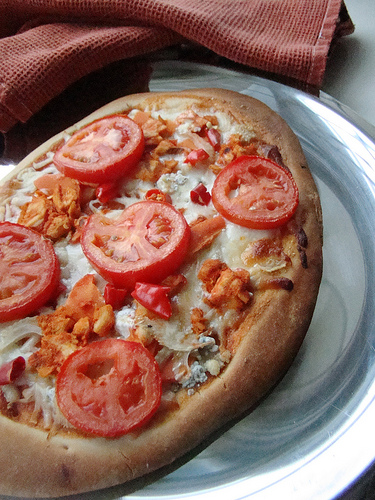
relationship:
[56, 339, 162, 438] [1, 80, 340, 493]
tomato atop pizza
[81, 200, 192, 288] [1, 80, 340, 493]
tomato atop pizza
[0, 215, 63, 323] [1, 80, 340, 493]
tomato atop pizza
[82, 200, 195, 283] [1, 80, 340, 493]
tomato atop pizza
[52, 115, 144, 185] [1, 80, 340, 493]
tomato atop pizza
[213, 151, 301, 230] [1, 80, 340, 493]
tomato atop pizza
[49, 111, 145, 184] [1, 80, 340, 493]
tomato atop pizza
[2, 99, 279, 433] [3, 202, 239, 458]
cheese atop pizza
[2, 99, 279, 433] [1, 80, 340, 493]
cheese on top pizza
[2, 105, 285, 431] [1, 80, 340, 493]
cheese melted on top pizza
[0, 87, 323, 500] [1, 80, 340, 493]
crust on pizza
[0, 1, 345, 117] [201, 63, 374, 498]
handcloth for plate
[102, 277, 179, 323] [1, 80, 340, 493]
pepper on pizza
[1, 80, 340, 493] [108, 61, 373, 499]
pizza on plate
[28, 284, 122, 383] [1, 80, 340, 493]
meat on pizza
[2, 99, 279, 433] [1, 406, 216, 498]
cheese on crust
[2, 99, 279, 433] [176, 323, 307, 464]
cheese on crust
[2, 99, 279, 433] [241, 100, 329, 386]
cheese on crust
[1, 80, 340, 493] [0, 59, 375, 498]
pizza on plate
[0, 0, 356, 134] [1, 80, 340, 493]
cloth by pizza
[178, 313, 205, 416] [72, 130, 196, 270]
blue cheese on top of pizza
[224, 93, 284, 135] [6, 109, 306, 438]
crust with toppings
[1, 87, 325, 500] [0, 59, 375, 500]
pizza on plate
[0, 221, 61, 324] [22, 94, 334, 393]
tomato on pizza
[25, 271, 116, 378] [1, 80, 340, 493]
bacon on pizza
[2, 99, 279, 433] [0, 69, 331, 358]
cheese on pizza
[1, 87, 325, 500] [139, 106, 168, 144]
pizza has topping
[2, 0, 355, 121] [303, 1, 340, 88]
cloth has trim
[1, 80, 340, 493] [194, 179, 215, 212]
pizza has peppers